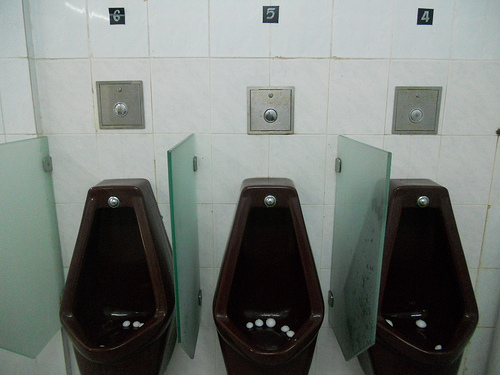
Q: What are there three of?
A: Three urinals on a wall.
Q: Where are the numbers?
A: Above the urinals.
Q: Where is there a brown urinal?
A: In the middle.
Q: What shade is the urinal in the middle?
A: Brown.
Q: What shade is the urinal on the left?
A: Brown.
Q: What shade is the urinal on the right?
A: Brown.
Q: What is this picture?
A: A number of urinals in the bathroom.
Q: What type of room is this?
A: Bathroom.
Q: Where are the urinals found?
A: In a bathroom.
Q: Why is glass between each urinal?
A: To prevent splashing.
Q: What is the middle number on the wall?
A: 5.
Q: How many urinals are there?
A: Three.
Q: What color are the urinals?
A: Brown.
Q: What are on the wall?
A: Tiles.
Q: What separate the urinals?
A: Glass.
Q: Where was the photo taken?
A: In a washroom.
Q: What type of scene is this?
A: Indoor.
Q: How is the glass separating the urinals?
A: Translucent.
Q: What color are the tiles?
A: White.